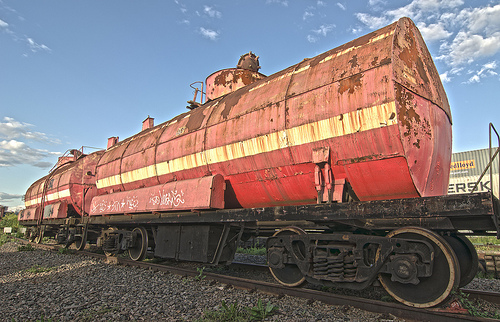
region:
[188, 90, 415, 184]
red and yellow car in train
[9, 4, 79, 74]
white clouds in blue sky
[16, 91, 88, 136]
white clouds in blue sky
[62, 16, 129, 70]
white clouds in blue sky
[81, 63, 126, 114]
white clouds in blue sky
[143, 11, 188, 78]
white clouds in blue sky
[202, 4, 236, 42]
white clouds in blue sky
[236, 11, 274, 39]
white clouds in blue sky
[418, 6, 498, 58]
white clouds in blue sky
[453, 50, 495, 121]
white clouds in blue sky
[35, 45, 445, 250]
Two long red and yellow tanker cars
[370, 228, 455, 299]
Large railroad car wheel on track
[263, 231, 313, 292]
Large railroad car wheel on track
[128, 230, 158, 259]
Large railroad car wheel on track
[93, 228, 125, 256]
Large railroad car wheel on track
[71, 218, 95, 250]
Large railroad car wheel on track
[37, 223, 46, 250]
Large railroad car wheel on track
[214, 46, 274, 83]
Opening on top of tanker car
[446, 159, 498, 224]
Metal shipping containers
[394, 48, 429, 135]
Rust building on sides of car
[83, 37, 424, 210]
red and yellow cargo car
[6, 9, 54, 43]
white clouds in blue sky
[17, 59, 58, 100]
white clouds in blue sky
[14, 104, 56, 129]
white clouds in blue sky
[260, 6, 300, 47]
white clouds in blue sky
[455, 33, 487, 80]
white clouds in blue sky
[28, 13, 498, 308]
two old tanker cars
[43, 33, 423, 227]
the car is very rusty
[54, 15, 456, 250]
the car is red with a yellow stripe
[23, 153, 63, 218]
a ladder goes up the side of the car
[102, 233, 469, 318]
the train is setting on the tracks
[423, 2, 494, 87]
light & fluffy clouds are in the sky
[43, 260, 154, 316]
gravel is to the side of the track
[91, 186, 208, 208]
grafitti is painted on the side of the car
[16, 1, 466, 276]
these tankers appear not to be usable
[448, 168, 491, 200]
the letters ERSK are on the building behind the train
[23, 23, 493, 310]
red train on train tracks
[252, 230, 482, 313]
wheels of a train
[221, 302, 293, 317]
grass growing in gravel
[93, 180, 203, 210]
graffiti on side of train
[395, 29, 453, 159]
rust on the back of train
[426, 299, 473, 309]
brakes to keep the train from rolling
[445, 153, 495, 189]
building behind train on track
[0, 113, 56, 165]
clouds in the sky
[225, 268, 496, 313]
train tracks where trains drive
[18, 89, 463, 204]
train carrying materials in carts